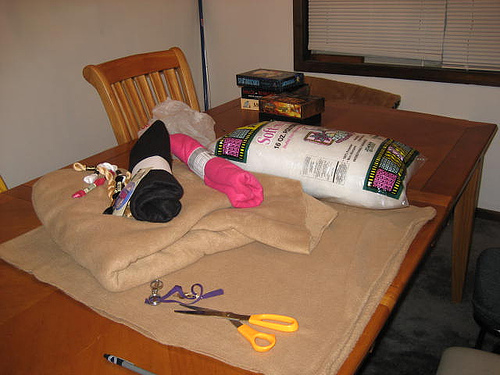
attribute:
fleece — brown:
[57, 122, 351, 350]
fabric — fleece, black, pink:
[120, 115, 276, 212]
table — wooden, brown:
[197, 86, 499, 215]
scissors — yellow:
[181, 309, 307, 356]